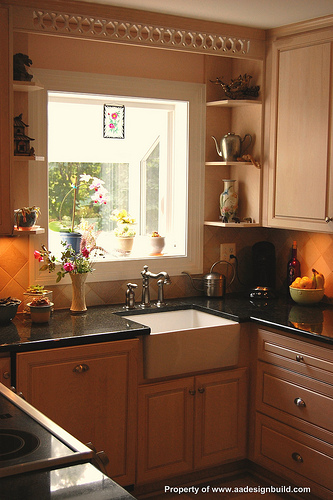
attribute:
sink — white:
[122, 304, 241, 382]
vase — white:
[68, 271, 92, 312]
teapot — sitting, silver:
[210, 133, 251, 161]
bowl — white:
[291, 285, 323, 305]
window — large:
[45, 92, 188, 264]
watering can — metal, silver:
[195, 258, 238, 301]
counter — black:
[0, 293, 332, 352]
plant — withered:
[208, 73, 262, 97]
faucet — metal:
[123, 264, 169, 309]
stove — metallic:
[2, 381, 93, 481]